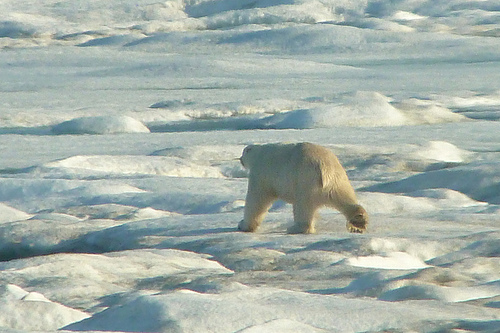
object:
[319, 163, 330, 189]
tail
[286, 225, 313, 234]
paw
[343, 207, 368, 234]
foot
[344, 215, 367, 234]
rear paw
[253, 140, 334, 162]
back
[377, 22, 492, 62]
ice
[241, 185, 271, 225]
leg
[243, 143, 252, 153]
ear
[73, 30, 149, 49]
snow hill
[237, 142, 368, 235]
bear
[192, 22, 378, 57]
snow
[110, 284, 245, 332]
ice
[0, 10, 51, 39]
wall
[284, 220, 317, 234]
foot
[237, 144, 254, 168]
head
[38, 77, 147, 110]
ice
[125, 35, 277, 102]
ice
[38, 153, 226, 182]
ice heap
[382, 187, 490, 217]
snow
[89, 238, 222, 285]
ground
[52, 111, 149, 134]
hill